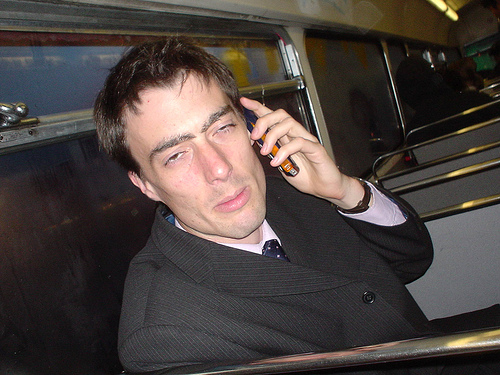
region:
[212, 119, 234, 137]
it is the left eye of the man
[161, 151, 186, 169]
it is the right eye of the man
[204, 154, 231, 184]
it is the nose of the man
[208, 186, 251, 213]
the mans lips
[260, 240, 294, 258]
man is wearing a blue tie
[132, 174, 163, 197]
it is the ear of the man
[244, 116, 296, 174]
man is on the phone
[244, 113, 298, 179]
man is holding an orange and black phone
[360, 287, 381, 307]
black button on the suit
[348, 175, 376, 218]
a black watch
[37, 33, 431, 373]
this man barely has his eyes open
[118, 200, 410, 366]
he is dressed in a suit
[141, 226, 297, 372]
the suit has pinstripes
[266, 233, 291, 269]
his tie is dark blue with little dots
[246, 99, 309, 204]
he appears to be holding a cell phone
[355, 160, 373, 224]
he is wearing a wrist watch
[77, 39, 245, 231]
he has short hair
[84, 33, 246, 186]
his hair is brown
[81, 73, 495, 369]
he appears to be sitting in public transportation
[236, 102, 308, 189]
the cell phone is yellow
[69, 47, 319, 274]
a man on the phone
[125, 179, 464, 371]
man wearing a suit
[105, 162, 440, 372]
THIS MAN IS WEARING A BLACK JACKET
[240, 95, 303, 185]
THIS MAN HAS A PHONE IN HIS HAND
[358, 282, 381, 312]
THIS BUTTON IS BLACK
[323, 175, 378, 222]
THIS MAN IS WEARING A WATCH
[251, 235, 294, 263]
THIS MAN IS WEARING A TIE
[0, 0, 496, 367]
THIS BUS IS DIRTY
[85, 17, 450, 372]
THIS MAN IS ON A BUS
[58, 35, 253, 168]
THIS MAN HAS SHORT HAIR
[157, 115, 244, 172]
THIS MAN'S EYES ARE SQUINTY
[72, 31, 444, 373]
THIS MAN IS TALKING ON THE PHONE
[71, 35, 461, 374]
A man sitting on the bus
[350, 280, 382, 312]
The button on the man's jacket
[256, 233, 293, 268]
The man has on a blue polka dot tie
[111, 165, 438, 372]
The man is wearing a blazer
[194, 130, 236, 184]
The nose of the man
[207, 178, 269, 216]
The mouth of the man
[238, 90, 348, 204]
The hand of the man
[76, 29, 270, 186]
The man has brown hair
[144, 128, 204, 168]
The eye of the man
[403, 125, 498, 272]
The empty seats on the bus